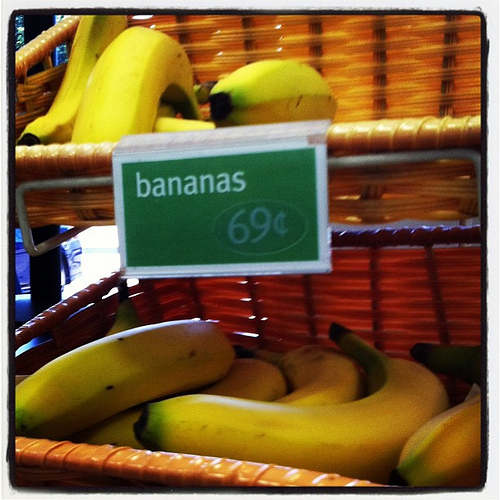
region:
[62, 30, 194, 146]
a ripe yellow banana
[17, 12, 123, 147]
a ripe yellow banana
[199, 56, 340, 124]
a ripe yellow banana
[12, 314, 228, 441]
a ripe yellow banana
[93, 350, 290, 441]
a ripe yellow banana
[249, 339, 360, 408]
a ripe yellow banana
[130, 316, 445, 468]
a ripe yellow banana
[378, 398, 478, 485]
a ripe yellow banana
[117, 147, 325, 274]
a price advertising sign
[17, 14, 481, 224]
a brown wicker basket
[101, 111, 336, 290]
a sale sign for bananas.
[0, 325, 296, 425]
a banana on a shelf.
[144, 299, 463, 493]
a long yellow banana.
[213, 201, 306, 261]
a 69 cent sign on bananas.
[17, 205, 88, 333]
a metal pole on a rack.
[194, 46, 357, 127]
a banana on a shelf.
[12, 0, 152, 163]
a banana on a rack.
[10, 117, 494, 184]
a banana on a shelf.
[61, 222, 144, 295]
light coming through a window.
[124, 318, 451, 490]
a yellow banana in a basket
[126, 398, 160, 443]
the end of a banana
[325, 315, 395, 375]
the stem of a banana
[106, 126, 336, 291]
a white and green sign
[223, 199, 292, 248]
a price tag on the sign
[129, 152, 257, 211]
white writing on the sign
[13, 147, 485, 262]
a gray metal rack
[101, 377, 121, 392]
a black spot on the banana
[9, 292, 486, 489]
bananas in a basket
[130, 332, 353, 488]
the bananas are visible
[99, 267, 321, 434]
the bananas are visible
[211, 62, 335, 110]
yellow banana on shelf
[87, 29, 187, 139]
yellow banana on shelf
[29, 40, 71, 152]
yellow banana on shelf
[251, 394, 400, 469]
yellow banana on shelf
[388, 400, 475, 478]
yellow banana in basket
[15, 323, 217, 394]
yellow banana in basket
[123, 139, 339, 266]
bananas price sign in green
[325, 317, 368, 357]
stem of yellow banana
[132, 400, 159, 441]
end of yellow banana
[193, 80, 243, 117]
end of yellow banana